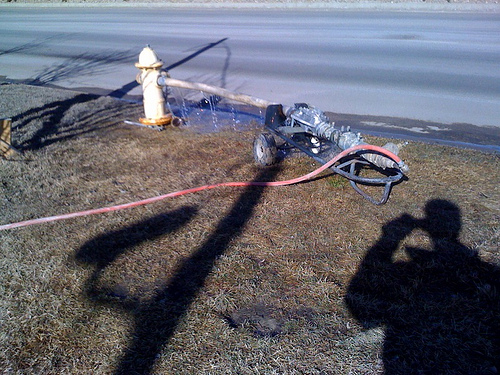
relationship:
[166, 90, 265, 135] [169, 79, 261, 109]
water dripping from hose